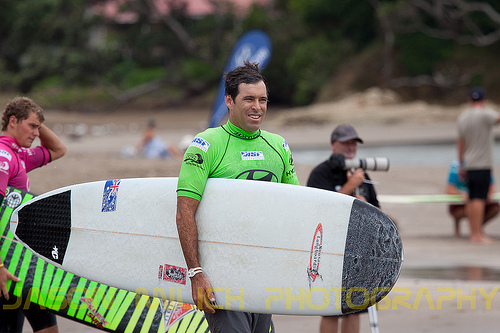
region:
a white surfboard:
[5, 175, 405, 312]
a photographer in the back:
[305, 119, 392, 329]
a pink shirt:
[0, 135, 51, 195]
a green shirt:
[174, 117, 304, 209]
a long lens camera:
[335, 153, 392, 183]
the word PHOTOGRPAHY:
[262, 283, 498, 318]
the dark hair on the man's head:
[221, 60, 261, 98]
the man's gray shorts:
[199, 299, 279, 331]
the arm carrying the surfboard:
[183, 121, 225, 312]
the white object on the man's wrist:
[182, 260, 204, 276]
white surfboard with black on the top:
[18, 179, 405, 307]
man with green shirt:
[167, 49, 291, 329]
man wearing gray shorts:
[178, 50, 308, 326]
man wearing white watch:
[175, 44, 298, 323]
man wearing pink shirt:
[1, 89, 58, 328]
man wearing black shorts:
[0, 87, 69, 329]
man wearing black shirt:
[305, 117, 403, 328]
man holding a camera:
[312, 115, 393, 332]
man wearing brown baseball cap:
[305, 108, 393, 331]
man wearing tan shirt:
[450, 68, 494, 242]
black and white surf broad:
[10, 175, 401, 315]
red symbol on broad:
[300, 225, 325, 285]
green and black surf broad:
[25, 280, 135, 310]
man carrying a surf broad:
[12, 65, 422, 325]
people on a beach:
[5, 22, 480, 322]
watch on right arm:
[185, 260, 205, 280]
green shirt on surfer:
[165, 125, 302, 200]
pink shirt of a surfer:
[1, 139, 42, 192]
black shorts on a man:
[454, 169, 499, 203]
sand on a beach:
[421, 236, 499, 325]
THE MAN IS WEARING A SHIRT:
[0, 131, 55, 206]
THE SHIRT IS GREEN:
[173, 117, 312, 227]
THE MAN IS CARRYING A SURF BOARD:
[11, 173, 406, 319]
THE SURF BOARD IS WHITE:
[8, 170, 412, 320]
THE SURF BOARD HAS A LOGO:
[297, 211, 330, 302]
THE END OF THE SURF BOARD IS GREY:
[335, 195, 405, 315]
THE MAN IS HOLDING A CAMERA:
[328, 148, 398, 186]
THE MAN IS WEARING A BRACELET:
[183, 260, 208, 285]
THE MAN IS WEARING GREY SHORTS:
[199, 301, 279, 331]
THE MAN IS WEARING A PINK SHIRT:
[0, 128, 60, 203]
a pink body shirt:
[2, 142, 37, 187]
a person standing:
[454, 118, 499, 244]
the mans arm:
[177, 194, 196, 275]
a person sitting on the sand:
[138, 121, 177, 164]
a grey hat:
[331, 125, 364, 143]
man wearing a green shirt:
[201, 133, 288, 183]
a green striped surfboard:
[6, 288, 128, 310]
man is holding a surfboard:
[103, 190, 408, 297]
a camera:
[341, 154, 389, 179]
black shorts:
[466, 170, 487, 196]